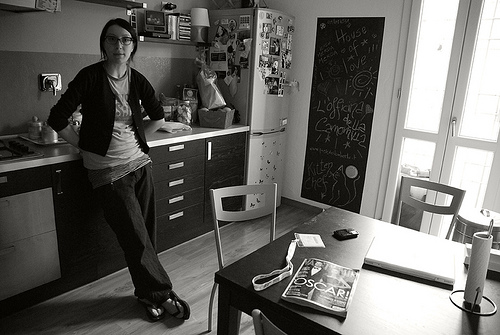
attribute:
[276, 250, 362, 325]
magazine — entertainment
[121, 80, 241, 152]
counter — kitchen 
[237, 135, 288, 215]
freezer section — freezer   